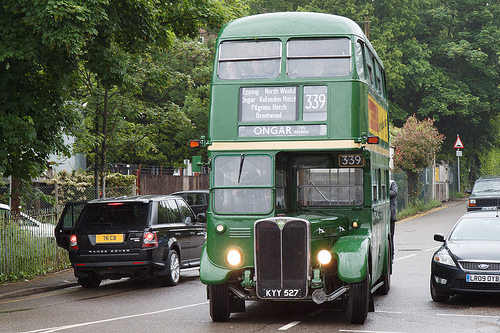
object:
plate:
[264, 288, 298, 296]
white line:
[279, 319, 306, 331]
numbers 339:
[304, 93, 325, 109]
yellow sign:
[367, 93, 389, 142]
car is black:
[429, 208, 498, 303]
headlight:
[225, 248, 243, 267]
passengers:
[221, 49, 343, 76]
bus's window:
[216, 39, 280, 79]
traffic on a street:
[0, 0, 496, 333]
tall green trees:
[3, 0, 247, 260]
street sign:
[452, 132, 464, 148]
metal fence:
[3, 187, 123, 273]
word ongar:
[252, 125, 292, 135]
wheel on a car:
[430, 275, 450, 302]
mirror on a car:
[433, 234, 444, 241]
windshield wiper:
[237, 154, 244, 183]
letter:
[265, 289, 281, 297]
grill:
[254, 218, 307, 298]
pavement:
[1, 194, 498, 331]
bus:
[198, 10, 399, 322]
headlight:
[317, 249, 331, 264]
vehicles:
[466, 174, 500, 209]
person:
[387, 164, 399, 277]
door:
[49, 199, 89, 249]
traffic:
[50, 7, 500, 327]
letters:
[240, 85, 327, 134]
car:
[49, 191, 214, 291]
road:
[0, 199, 500, 328]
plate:
[93, 232, 125, 244]